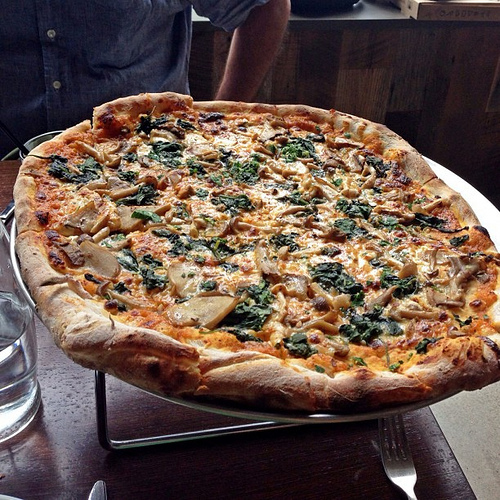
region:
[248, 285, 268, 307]
green spinach on pizza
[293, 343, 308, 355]
green spinach on pizza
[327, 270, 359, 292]
green spinach on pizza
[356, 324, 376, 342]
green spinach on pizza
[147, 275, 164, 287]
green spinach on pizza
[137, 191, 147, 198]
green spinach on pizza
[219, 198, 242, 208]
green spinach on pizza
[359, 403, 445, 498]
a shiny silver fork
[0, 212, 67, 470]
a half full water container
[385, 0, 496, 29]
a light wood tray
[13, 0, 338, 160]
a man in a blue shirt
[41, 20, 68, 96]
a couple white buttons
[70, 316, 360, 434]
a dry pizza crust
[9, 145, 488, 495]
a dark wood table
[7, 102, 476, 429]
a uncut vegetable pizza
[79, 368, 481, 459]
a metal pizza stand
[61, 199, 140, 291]
a few pieces of mushroom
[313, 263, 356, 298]
green spinach on pizza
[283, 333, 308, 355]
green spinach on pizza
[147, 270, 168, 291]
green spinach on pizza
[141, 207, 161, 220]
green spinach on pizza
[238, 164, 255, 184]
green spinach on pizza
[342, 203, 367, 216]
green spinach on pizza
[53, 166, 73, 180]
green spinach on pizza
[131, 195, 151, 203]
green spinach on pizza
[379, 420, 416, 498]
the silver fork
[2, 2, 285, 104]
the man sitting at the table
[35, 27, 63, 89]
the buttons on the man's shirt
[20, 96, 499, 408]
the large round pizza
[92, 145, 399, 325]
the toppings on the pizza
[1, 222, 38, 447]
the clear glass container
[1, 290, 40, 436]
the liquid in the glass container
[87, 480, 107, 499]
the top of a butter knife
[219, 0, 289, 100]
the forearm on the man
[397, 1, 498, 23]
the cardboard box in the back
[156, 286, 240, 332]
a mushroom slice on a pizza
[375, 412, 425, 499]
a fork on a table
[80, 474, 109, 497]
the visible tip of a knife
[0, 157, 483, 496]
a dark brown table under a pizza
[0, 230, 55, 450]
a glass of water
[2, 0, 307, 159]
a brown denim shirt on a man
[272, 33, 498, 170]
a brown wood wall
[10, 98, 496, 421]
a large round pizza pan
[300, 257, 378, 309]
spinach on a pizza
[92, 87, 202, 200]
a lifted up piece of pizza